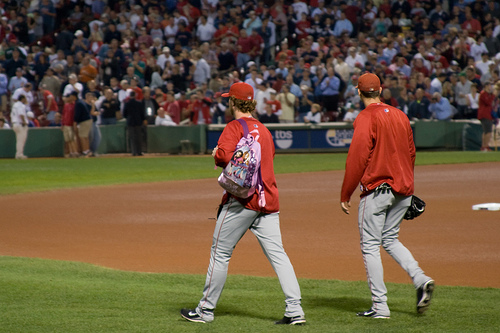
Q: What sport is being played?
A: Baseball.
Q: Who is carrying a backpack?
A: The guy on the left.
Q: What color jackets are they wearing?
A: Red.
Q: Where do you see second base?
A: Far right side of the picture.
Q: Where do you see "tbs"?
A: On the wall behind the players.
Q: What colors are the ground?
A: Green and Brown.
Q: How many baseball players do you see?
A: 2.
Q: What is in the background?
A: Fans.